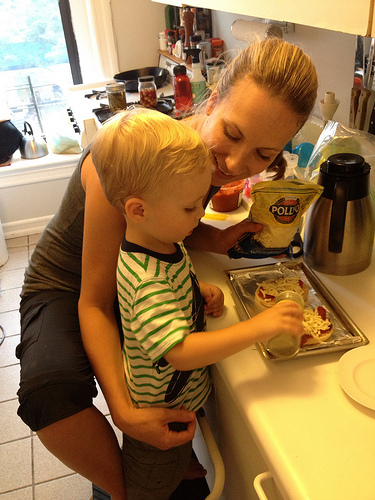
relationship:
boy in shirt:
[90, 104, 304, 500] [109, 231, 214, 427]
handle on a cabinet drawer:
[244, 467, 288, 499] [201, 370, 295, 498]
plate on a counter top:
[332, 339, 362, 418] [298, 274, 362, 490]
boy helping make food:
[90, 104, 304, 500] [227, 254, 350, 356]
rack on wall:
[221, 16, 290, 45] [202, 11, 342, 116]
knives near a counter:
[354, 34, 374, 89] [311, 119, 363, 146]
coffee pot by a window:
[19, 121, 48, 159] [0, 1, 115, 161]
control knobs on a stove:
[60, 98, 83, 142] [3, 99, 103, 163]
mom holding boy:
[15, 25, 318, 500] [90, 104, 304, 500]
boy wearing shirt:
[90, 104, 304, 500] [115, 235, 216, 423]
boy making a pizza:
[90, 104, 304, 500] [225, 254, 358, 362]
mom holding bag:
[15, 25, 318, 500] [239, 171, 328, 249]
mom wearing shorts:
[15, 25, 318, 500] [16, 276, 245, 449]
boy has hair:
[90, 104, 304, 500] [71, 96, 212, 191]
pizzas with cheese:
[255, 273, 310, 307] [262, 281, 298, 293]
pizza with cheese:
[281, 303, 338, 350] [301, 312, 327, 334]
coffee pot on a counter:
[298, 150, 362, 284] [186, 250, 375, 500]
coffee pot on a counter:
[14, 117, 48, 162] [4, 143, 81, 173]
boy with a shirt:
[90, 104, 304, 500] [115, 235, 216, 423]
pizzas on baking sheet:
[254, 272, 330, 340] [222, 257, 369, 362]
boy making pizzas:
[90, 104, 304, 500] [254, 272, 330, 340]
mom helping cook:
[207, 45, 294, 187] [242, 266, 346, 351]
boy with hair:
[90, 104, 304, 500] [82, 98, 221, 256]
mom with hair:
[15, 25, 318, 500] [32, 37, 328, 481]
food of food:
[105, 82, 127, 113] [97, 57, 139, 121]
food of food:
[138, 76, 157, 110] [126, 70, 167, 112]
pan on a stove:
[105, 53, 191, 103] [58, 28, 238, 145]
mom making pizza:
[15, 25, 318, 500] [300, 304, 333, 348]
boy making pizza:
[90, 104, 304, 500] [300, 304, 333, 348]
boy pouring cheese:
[90, 104, 304, 500] [265, 282, 314, 369]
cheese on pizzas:
[265, 282, 314, 369] [252, 260, 324, 372]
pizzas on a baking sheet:
[255, 273, 310, 307] [222, 257, 369, 362]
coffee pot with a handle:
[19, 121, 48, 159] [13, 103, 40, 138]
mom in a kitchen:
[15, 25, 318, 500] [1, 12, 354, 498]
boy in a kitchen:
[90, 104, 304, 500] [1, 12, 354, 498]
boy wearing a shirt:
[76, 95, 248, 464] [87, 246, 240, 417]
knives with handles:
[338, 42, 374, 137] [345, 91, 372, 116]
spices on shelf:
[145, 7, 205, 74] [141, 9, 218, 97]